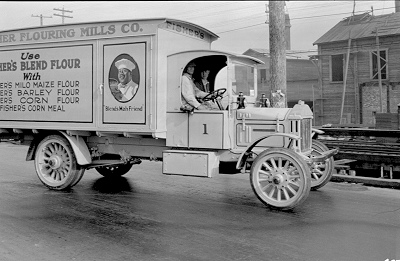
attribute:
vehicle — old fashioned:
[3, 10, 354, 217]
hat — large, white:
[186, 59, 203, 78]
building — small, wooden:
[305, 7, 398, 133]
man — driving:
[180, 62, 224, 109]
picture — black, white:
[11, 13, 399, 238]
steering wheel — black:
[200, 87, 226, 99]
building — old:
[303, 12, 383, 133]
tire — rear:
[46, 139, 94, 190]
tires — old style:
[28, 134, 90, 190]